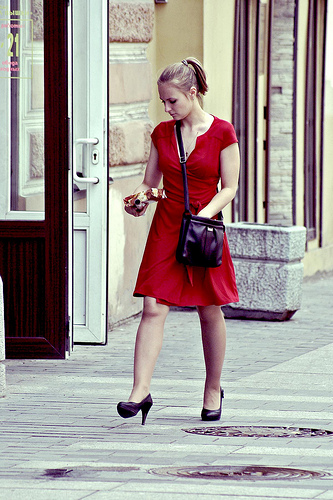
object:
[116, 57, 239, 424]
woman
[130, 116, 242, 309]
red dress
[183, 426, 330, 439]
manhole cover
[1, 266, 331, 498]
sidewalk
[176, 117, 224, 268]
purse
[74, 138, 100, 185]
handle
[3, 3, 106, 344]
door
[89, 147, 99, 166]
keyhole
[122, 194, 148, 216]
hand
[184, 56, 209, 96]
ponytail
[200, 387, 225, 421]
heel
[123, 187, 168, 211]
paper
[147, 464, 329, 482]
manhole cover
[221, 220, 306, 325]
planter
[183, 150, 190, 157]
cross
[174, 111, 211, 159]
necklace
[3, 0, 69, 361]
door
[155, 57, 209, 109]
blonde hair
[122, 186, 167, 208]
wrapped package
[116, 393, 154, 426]
black shoe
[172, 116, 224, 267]
black purse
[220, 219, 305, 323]
trash can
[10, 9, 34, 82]
writing